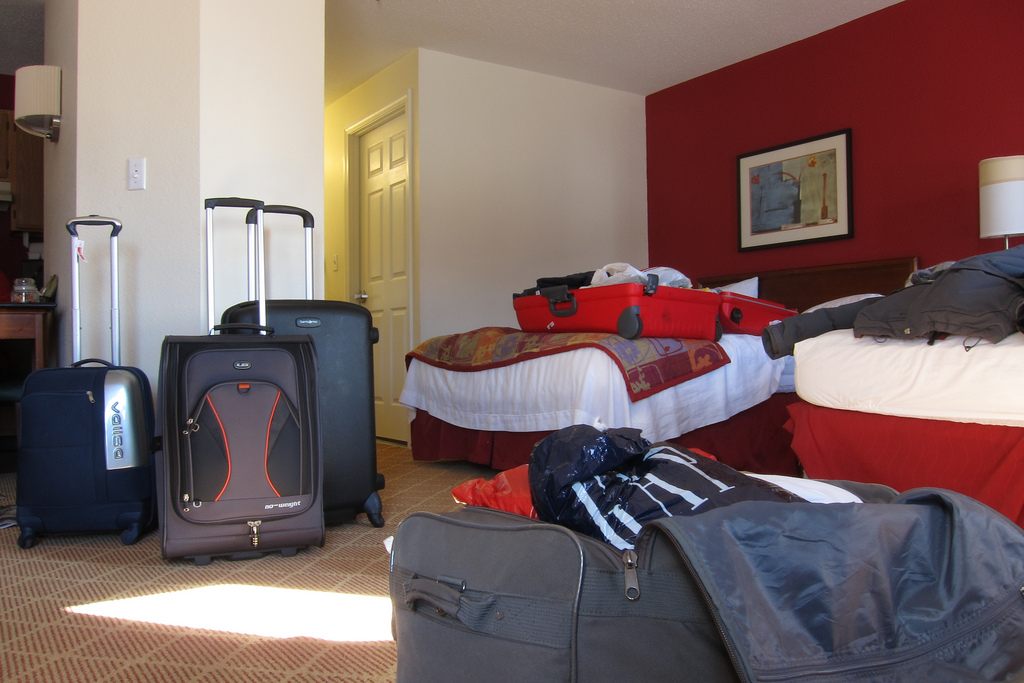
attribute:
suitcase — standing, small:
[9, 214, 162, 550]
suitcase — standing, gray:
[155, 198, 326, 560]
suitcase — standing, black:
[218, 203, 381, 526]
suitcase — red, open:
[509, 289, 802, 336]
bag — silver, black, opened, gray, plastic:
[390, 423, 1021, 677]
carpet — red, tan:
[0, 436, 520, 682]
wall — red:
[646, 3, 1023, 311]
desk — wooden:
[4, 302, 48, 383]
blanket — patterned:
[407, 326, 730, 404]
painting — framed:
[736, 128, 852, 254]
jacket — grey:
[763, 245, 1021, 365]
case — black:
[762, 295, 881, 360]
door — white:
[350, 91, 412, 446]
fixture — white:
[13, 63, 64, 144]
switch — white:
[125, 152, 150, 195]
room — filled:
[0, 3, 1019, 682]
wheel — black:
[122, 521, 146, 544]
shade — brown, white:
[976, 155, 1022, 237]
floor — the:
[2, 381, 504, 678]